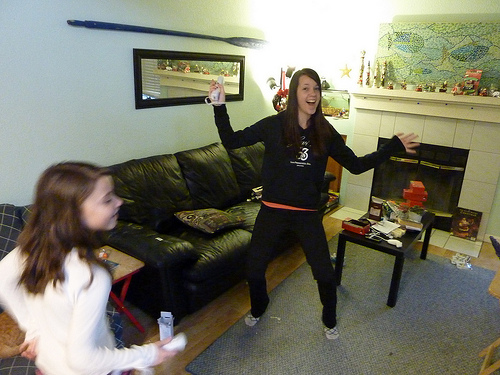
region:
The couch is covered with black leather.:
[120, 141, 260, 306]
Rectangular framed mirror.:
[130, 45, 245, 105]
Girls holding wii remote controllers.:
[150, 70, 225, 355]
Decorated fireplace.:
[330, 50, 495, 215]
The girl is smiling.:
[285, 60, 325, 120]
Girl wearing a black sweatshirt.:
[255, 110, 325, 205]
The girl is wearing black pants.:
[245, 205, 335, 325]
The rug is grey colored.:
[230, 270, 485, 370]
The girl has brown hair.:
[15, 155, 90, 290]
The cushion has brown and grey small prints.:
[175, 201, 241, 231]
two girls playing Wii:
[0, 65, 421, 374]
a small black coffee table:
[331, 194, 436, 307]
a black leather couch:
[93, 136, 268, 322]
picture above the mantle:
[375, 17, 498, 87]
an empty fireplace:
[370, 133, 472, 232]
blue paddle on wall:
[65, 13, 270, 53]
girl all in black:
[207, 65, 422, 339]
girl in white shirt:
[1, 158, 186, 374]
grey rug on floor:
[181, 230, 498, 372]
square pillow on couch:
[174, 208, 248, 236]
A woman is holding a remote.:
[186, 68, 351, 159]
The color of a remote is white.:
[190, 66, 239, 136]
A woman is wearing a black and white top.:
[200, 74, 412, 217]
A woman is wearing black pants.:
[233, 184, 350, 347]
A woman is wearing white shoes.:
[225, 293, 355, 348]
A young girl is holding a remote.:
[128, 283, 208, 372]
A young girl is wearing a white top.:
[0, 144, 196, 374]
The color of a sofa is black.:
[30, 117, 327, 344]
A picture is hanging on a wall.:
[118, 40, 250, 116]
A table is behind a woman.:
[325, 165, 442, 329]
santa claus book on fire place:
[443, 203, 480, 244]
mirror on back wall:
[131, 49, 246, 105]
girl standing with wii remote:
[193, 69, 427, 371]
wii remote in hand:
[148, 333, 200, 366]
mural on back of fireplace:
[376, 25, 498, 81]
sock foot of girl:
[319, 325, 341, 345]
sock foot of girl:
[241, 307, 266, 329]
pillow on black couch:
[181, 202, 236, 235]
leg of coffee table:
[378, 252, 403, 312]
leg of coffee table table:
[328, 231, 352, 288]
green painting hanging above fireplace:
[350, 18, 495, 88]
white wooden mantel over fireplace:
[342, 71, 497, 138]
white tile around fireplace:
[343, 113, 498, 230]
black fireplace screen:
[375, 137, 464, 214]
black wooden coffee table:
[325, 179, 444, 310]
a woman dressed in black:
[201, 45, 387, 359]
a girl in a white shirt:
[15, 149, 149, 373]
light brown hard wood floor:
[188, 291, 230, 346]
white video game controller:
[198, 72, 232, 115]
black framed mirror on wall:
[115, 41, 254, 110]